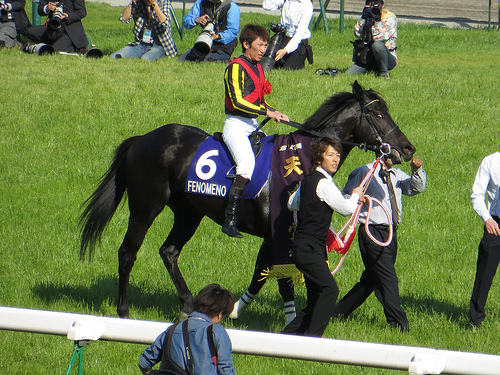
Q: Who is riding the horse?
A: The man with the red and black vest.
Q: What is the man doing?
A: Riding a horse.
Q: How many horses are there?
A: One.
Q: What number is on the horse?
A: Six.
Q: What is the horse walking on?
A: Grass.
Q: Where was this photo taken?
A: At a horse race.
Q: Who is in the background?
A: Photographers.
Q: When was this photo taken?
A: During the daytime.